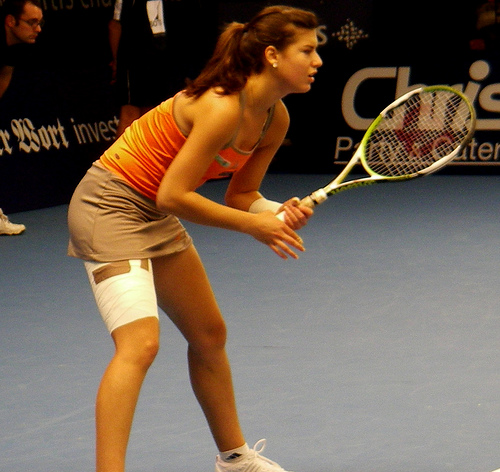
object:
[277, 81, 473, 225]
racket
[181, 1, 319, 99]
hair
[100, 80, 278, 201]
shirt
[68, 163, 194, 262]
skirt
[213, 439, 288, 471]
shoe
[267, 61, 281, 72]
earring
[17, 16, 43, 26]
glasses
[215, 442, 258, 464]
sock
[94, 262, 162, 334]
wrap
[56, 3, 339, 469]
woman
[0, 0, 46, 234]
man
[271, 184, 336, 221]
grip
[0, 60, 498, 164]
sign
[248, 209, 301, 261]
hand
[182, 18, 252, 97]
pony tail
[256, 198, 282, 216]
wristband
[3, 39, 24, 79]
shirt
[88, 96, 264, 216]
tank top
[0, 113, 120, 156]
ad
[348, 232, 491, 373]
court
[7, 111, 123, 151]
words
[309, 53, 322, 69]
nose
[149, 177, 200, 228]
elbow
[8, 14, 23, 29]
sideburns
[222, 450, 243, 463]
logo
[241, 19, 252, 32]
band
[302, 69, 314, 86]
mouth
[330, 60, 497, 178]
banner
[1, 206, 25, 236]
shoe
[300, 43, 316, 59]
eye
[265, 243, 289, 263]
fingers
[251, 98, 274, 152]
strap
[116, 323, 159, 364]
knees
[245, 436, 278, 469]
lace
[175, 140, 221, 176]
bicep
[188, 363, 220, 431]
calve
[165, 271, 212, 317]
thigh